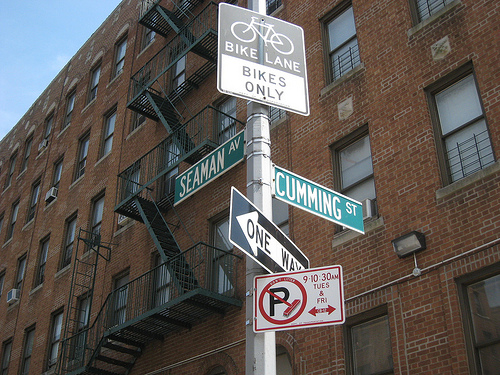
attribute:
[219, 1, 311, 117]
sign — bikes only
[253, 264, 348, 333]
sign — red, white, street cleaning, no parking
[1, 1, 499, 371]
building — brick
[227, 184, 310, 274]
sign — one way, black, white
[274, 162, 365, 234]
sign — cumming st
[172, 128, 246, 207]
sign — seaman av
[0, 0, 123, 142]
sky — blue